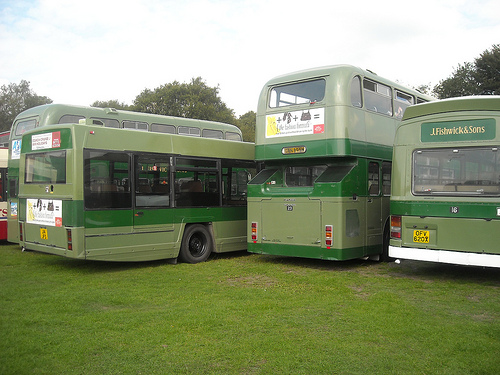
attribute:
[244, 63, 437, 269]
busses — green, double decker, parked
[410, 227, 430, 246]
license plate — yellow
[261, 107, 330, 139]
sign — white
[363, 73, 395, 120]
windows — large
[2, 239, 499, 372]
grass — green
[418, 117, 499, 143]
sign — yellow lettered, logo, green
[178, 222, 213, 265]
tire — black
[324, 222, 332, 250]
taillights — rectangular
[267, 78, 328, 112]
window — rectangular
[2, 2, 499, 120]
sky — cloudy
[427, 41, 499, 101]
trees — green, dark green